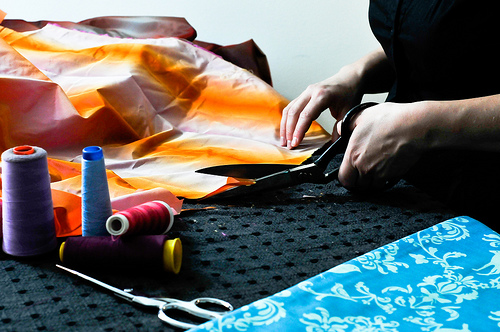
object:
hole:
[235, 268, 247, 275]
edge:
[463, 215, 500, 242]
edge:
[195, 170, 260, 180]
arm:
[405, 95, 499, 149]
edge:
[380, 89, 500, 106]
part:
[300, 94, 321, 122]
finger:
[290, 96, 327, 148]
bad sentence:
[296, 246, 304, 252]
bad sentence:
[273, 227, 285, 233]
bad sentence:
[294, 225, 308, 231]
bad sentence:
[337, 219, 353, 225]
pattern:
[488, 307, 500, 328]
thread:
[110, 198, 170, 238]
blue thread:
[78, 147, 117, 238]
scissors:
[55, 261, 236, 329]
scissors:
[193, 101, 380, 205]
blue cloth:
[184, 216, 500, 331]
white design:
[471, 230, 499, 279]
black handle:
[315, 101, 378, 172]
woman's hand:
[330, 99, 432, 192]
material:
[0, 23, 338, 239]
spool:
[55, 237, 189, 275]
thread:
[63, 232, 169, 274]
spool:
[7, 142, 38, 158]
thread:
[4, 142, 57, 258]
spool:
[79, 147, 110, 161]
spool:
[103, 199, 175, 236]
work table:
[6, 160, 499, 332]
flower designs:
[196, 286, 295, 331]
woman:
[280, 0, 500, 192]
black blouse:
[366, 0, 500, 109]